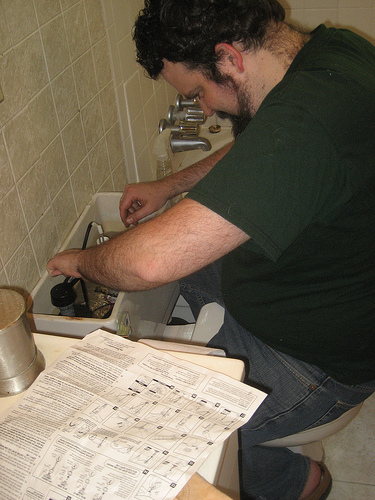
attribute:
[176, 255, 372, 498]
jeans — blue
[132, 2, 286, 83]
hair — thick, black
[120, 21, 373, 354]
shirt — green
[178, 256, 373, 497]
pants — jean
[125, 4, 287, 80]
hair — brown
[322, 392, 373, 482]
tile — white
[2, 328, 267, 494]
paper — large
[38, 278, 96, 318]
knob — black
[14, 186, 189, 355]
toilet tank — open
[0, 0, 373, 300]
tiles — ceramic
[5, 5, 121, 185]
wall — tiled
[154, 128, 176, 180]
bottle — soap bottle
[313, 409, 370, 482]
floor — marbalized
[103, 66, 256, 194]
faucet — complicated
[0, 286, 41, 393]
bowl — silver, large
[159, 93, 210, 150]
faucet — silver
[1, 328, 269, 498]
diagram — complicated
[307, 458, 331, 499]
shoes — brown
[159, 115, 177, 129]
taps — silver